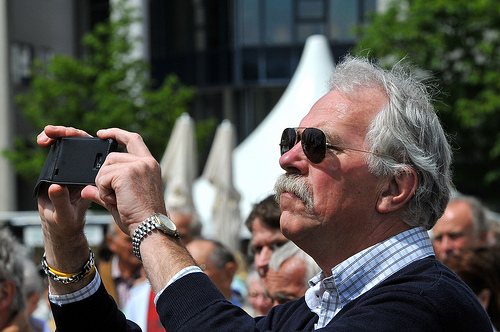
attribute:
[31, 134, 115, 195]
camera — black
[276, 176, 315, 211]
mustache — gray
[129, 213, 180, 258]
watch — gold, metal, silver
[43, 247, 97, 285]
bracelet — silver, white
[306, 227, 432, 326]
shirt — checkered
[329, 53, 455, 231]
hair — silver, gray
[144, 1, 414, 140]
building — tall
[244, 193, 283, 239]
hair — brown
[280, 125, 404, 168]
sunglasses — black, dark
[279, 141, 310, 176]
nose — red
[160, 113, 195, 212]
umbrella — collapsed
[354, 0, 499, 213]
tree — green, leafy